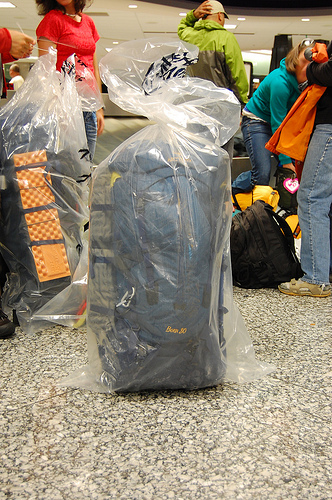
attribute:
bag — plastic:
[72, 73, 263, 435]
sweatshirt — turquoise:
[239, 59, 303, 168]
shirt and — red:
[35, 9, 100, 162]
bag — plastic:
[7, 45, 90, 328]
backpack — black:
[229, 199, 302, 288]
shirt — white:
[30, 13, 114, 99]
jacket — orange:
[263, 48, 329, 162]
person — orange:
[274, 31, 330, 298]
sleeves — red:
[0, 26, 11, 62]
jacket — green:
[165, 10, 257, 109]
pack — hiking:
[91, 138, 231, 392]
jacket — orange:
[264, 35, 321, 166]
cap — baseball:
[192, 1, 236, 20]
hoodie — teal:
[245, 54, 305, 166]